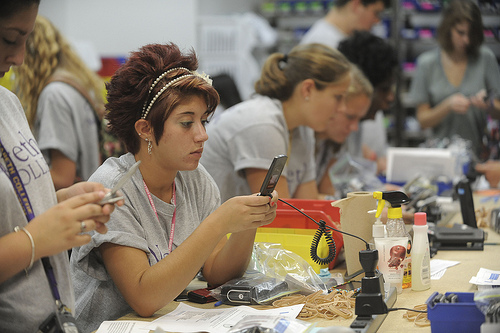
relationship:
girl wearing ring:
[2, 1, 118, 331] [75, 220, 89, 235]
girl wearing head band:
[67, 44, 279, 333] [140, 67, 213, 119]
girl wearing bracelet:
[2, 1, 118, 331] [10, 211, 38, 282]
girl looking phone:
[67, 44, 279, 333] [256, 152, 288, 197]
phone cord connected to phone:
[234, 143, 384, 300] [258, 154, 289, 195]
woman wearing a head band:
[68, 39, 278, 333] [140, 67, 213, 119]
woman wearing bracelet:
[2, 0, 121, 330] [12, 225, 35, 273]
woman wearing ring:
[2, 0, 121, 330] [79, 221, 86, 232]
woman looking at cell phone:
[68, 39, 278, 333] [259, 152, 284, 195]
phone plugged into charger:
[251, 153, 289, 199] [263, 191, 385, 313]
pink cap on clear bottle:
[409, 208, 433, 226] [410, 223, 434, 287]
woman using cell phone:
[68, 39, 278, 333] [257, 153, 291, 197]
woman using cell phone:
[68, 39, 278, 333] [100, 159, 140, 204]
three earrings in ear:
[136, 133, 152, 153] [133, 120, 150, 141]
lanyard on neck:
[137, 172, 186, 258] [132, 139, 178, 196]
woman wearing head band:
[100, 39, 261, 311] [136, 66, 213, 115]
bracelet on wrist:
[15, 224, 37, 289] [1, 215, 45, 285]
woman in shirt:
[420, 33, 498, 163] [410, 52, 484, 137]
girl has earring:
[67, 45, 317, 327] [146, 132, 160, 163]